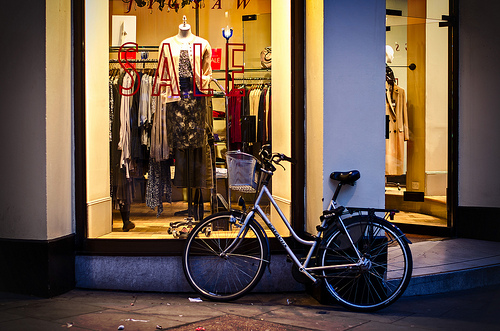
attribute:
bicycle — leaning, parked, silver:
[182, 145, 418, 313]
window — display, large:
[112, 1, 283, 234]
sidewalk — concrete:
[64, 290, 191, 330]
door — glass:
[386, 17, 448, 229]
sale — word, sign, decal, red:
[121, 37, 249, 104]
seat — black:
[329, 164, 361, 190]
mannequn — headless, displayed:
[150, 14, 220, 200]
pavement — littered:
[155, 300, 229, 330]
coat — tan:
[383, 80, 415, 178]